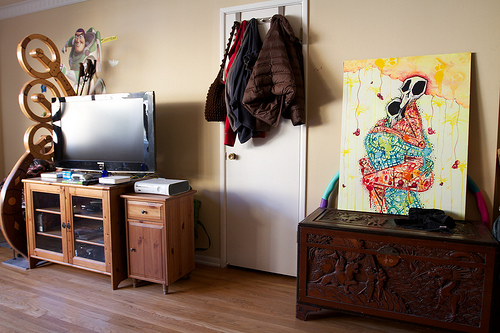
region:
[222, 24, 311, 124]
coats on door hooks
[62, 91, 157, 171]
black flat screen tv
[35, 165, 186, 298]
brown tables under tv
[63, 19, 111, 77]
sticker attached to wall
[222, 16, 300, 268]
white door behind coats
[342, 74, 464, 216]
yellow artwork on table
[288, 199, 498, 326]
table is cherry brown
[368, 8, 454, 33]
tan wall behind artwork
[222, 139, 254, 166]
gold handle on door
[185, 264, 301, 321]
floor is light brown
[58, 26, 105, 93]
poster of buzz lightyear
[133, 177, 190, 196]
xbox 360 on a small cabinet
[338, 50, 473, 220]
colorful abstract painting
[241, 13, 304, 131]
brown coat hanging on the door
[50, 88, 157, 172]
flat screen tv on the cabinet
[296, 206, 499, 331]
large wooden carved chest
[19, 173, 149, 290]
cabinet full of game consoles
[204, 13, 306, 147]
clothes and a purse on hooks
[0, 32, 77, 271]
brown wooden art statue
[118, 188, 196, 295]
small wooden cabinet next to tv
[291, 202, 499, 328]
carved wooden storage box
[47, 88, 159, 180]
large black flat screen television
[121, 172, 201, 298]
small wooden side cabinet with a game console on it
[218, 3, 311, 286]
white internal door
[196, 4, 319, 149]
jackets and a bag hanging on a door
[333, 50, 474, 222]
a colorful piece of artwork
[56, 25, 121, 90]
buzz lightyear wall decor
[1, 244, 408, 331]
wood panels on a floor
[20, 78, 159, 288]
glass fronted wooden cabinet with a tv on it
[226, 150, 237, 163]
gold colored door knob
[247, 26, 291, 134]
that is a jacket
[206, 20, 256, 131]
that is a jacket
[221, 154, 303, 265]
that is a door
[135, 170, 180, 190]
that is a book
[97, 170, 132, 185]
that is a book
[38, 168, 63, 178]
that is a book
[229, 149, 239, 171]
that is a knob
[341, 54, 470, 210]
that is a painting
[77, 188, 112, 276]
that is a chest of drawers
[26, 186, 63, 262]
that is a chest of drawers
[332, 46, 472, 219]
Painting of two skeletons hugging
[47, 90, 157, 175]
Black flatscreen television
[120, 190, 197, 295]
Brown wood end table with one drawer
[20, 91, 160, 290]
Wood entertainment stand with a television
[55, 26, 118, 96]
Buzz Lightyear fathead on the wall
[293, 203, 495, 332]
Dark brown carved wood chest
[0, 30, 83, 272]
Abstract wood sculpture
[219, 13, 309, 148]
Three coats hanging off a door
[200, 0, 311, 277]
White door with hanging coats and a purse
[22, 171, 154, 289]
Wood entertainment center with two glass doors